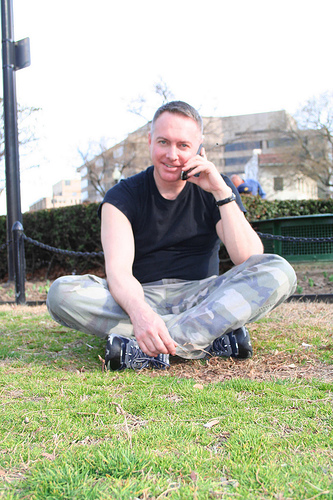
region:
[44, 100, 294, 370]
A man sitting on the ground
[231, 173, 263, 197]
A man in a blue jacket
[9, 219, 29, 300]
A black metal pylon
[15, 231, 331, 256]
A black chain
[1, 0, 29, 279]
A tall black metal pole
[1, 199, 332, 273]
A line of bushes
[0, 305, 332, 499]
A small grassy field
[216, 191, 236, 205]
A watch on the man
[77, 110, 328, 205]
A large stone building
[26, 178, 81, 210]
A large stone building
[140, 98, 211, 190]
The man is on the phone and smiling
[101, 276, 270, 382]
Wearing camoflage pants and hiking boots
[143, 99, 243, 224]
A man on a phone is wearing a wrist watch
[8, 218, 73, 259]
The fence is made of chain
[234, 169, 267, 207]
A mans bald head in the background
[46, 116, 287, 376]
Man is wearing camoflage pants and a black shirt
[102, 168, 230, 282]
A black shirt with no sleeves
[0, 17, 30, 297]
A tall metal pole painted black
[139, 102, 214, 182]
Man has a military style haircut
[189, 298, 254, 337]
Camoflage consists of greens, browns and black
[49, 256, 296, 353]
The man is wearng army pants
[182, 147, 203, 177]
The man has a cell phone in his hands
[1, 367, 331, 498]
Grass beneath the man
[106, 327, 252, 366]
The man is wearing black shoes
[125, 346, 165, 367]
The shoelaces are gray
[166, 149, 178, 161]
The nose of the man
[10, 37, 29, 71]
A sign on the post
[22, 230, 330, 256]
A chain behind the man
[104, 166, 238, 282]
The man is wearing a black shirt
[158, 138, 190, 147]
The eyes of the man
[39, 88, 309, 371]
man sitting on phone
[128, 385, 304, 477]
green grass of a lawn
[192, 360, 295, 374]
brown leaves in the grass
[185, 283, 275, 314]
camoflage pants on a man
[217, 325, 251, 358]
sneaker on man's foot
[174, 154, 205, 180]
phone in man's hand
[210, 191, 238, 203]
watch on man's wrist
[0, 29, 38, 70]
sign on a pole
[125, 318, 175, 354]
right hand of a man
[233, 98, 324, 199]
building behind a park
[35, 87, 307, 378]
man sits on grass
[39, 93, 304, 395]
man sits cross-feet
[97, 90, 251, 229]
man with short hair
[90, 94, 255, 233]
man holds a cell phone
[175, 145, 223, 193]
cell phone on hand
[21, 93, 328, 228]
a building behind a man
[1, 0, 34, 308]
a sign on a pole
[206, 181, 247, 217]
a watch on wrist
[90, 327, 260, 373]
shoes with gray pins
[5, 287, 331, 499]
field of green grass